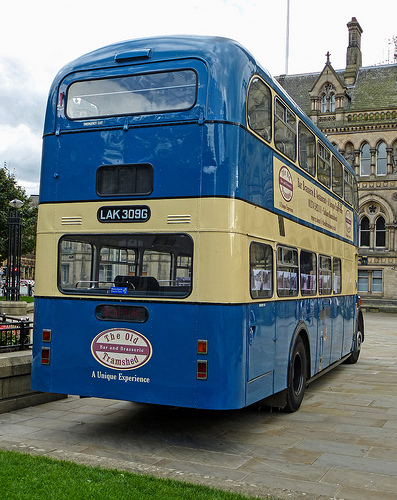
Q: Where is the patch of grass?
A: By the curb in the left foreground.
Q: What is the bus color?
A: Blue and cream.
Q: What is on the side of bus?
A: Sign.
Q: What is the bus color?
A: Blue and yellow.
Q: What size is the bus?
A: Large.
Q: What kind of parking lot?
A: Flagstone.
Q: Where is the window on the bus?
A: Back.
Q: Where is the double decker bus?
A: Outside a building.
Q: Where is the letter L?
A: On the train.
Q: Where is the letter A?
A: On the bus.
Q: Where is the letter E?
A: On the bus.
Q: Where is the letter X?
A: On the bus.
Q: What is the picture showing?
A: Bus.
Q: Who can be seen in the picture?
A: No one.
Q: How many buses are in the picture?
A: One.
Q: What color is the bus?
A: Blue and beige.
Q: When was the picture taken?
A: During the day.